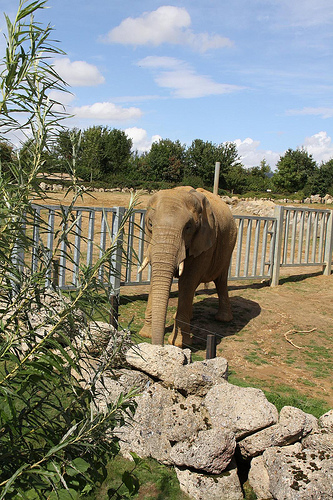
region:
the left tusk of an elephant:
[176, 259, 185, 277]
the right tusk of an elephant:
[133, 256, 150, 275]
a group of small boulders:
[97, 339, 328, 498]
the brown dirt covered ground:
[233, 289, 329, 383]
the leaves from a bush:
[4, 338, 117, 492]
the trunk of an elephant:
[148, 235, 175, 344]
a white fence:
[276, 205, 332, 280]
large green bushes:
[58, 124, 180, 187]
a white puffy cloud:
[97, 3, 239, 51]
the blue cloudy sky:
[4, 0, 331, 116]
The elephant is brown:
[135, 176, 245, 352]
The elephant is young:
[129, 187, 253, 350]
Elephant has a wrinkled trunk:
[147, 224, 164, 341]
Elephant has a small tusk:
[173, 253, 183, 275]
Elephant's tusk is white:
[175, 255, 185, 278]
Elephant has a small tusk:
[132, 247, 142, 274]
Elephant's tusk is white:
[135, 250, 148, 276]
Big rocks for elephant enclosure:
[118, 338, 262, 464]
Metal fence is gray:
[218, 198, 268, 282]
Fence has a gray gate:
[262, 197, 326, 278]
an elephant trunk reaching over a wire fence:
[149, 254, 173, 353]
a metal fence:
[37, 198, 328, 280]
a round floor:
[204, 154, 221, 202]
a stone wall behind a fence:
[6, 291, 327, 485]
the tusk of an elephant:
[127, 250, 147, 274]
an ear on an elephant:
[186, 192, 215, 262]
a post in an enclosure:
[207, 157, 224, 208]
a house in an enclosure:
[22, 166, 87, 191]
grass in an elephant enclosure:
[78, 292, 146, 319]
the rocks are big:
[234, 463, 270, 481]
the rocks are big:
[247, 451, 277, 489]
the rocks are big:
[270, 463, 284, 476]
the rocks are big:
[267, 445, 284, 469]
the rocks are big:
[266, 446, 271, 463]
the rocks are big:
[285, 459, 292, 477]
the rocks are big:
[278, 475, 289, 490]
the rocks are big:
[258, 459, 270, 489]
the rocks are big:
[278, 460, 290, 487]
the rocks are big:
[273, 473, 284, 486]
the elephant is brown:
[109, 163, 274, 376]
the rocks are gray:
[99, 319, 265, 496]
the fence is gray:
[68, 146, 326, 321]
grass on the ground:
[244, 294, 325, 383]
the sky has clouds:
[72, 27, 270, 135]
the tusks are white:
[120, 249, 214, 292]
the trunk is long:
[138, 243, 193, 376]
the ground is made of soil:
[85, 181, 157, 272]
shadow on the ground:
[165, 286, 272, 382]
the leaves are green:
[15, 103, 137, 488]